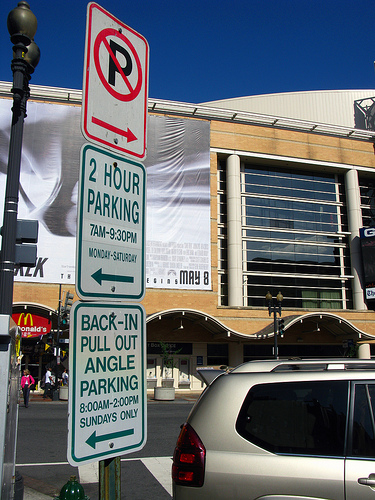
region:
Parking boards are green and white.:
[80, 161, 135, 427]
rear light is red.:
[167, 419, 218, 487]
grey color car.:
[179, 375, 372, 497]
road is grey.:
[32, 407, 56, 446]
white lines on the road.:
[140, 455, 173, 496]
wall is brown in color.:
[154, 293, 217, 311]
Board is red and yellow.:
[11, 306, 49, 351]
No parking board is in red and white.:
[87, 7, 159, 167]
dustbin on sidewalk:
[149, 384, 190, 409]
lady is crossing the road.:
[19, 371, 37, 398]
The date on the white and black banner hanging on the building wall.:
[176, 269, 212, 286]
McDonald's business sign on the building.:
[12, 309, 52, 337]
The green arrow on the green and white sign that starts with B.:
[81, 426, 141, 452]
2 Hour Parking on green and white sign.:
[87, 153, 145, 227]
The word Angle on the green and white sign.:
[83, 354, 140, 372]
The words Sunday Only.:
[79, 406, 141, 430]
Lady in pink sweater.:
[19, 364, 40, 407]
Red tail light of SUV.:
[162, 421, 208, 492]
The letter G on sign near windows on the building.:
[359, 225, 374, 237]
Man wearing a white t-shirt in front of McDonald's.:
[39, 361, 56, 402]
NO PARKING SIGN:
[79, 0, 157, 162]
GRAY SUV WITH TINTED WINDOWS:
[169, 351, 373, 498]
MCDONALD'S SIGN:
[5, 306, 55, 341]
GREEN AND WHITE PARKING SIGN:
[64, 300, 151, 467]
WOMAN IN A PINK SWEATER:
[17, 367, 38, 412]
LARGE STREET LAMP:
[2, 0, 46, 411]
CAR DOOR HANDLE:
[353, 470, 373, 493]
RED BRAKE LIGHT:
[166, 417, 210, 490]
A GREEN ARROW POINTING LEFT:
[85, 421, 139, 451]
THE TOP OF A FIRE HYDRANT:
[51, 472, 91, 496]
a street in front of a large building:
[27, 11, 342, 465]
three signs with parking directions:
[60, 0, 150, 473]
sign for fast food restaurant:
[0, 301, 57, 342]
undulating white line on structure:
[150, 300, 363, 372]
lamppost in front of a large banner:
[3, 0, 70, 325]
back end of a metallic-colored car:
[165, 336, 365, 486]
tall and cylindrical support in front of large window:
[206, 140, 262, 314]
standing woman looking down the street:
[16, 362, 38, 408]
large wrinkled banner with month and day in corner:
[153, 112, 214, 292]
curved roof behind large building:
[192, 77, 366, 144]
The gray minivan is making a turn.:
[164, 352, 374, 498]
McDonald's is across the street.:
[1, 290, 72, 391]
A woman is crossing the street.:
[16, 355, 43, 412]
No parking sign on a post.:
[70, 0, 154, 155]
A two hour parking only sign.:
[76, 150, 151, 305]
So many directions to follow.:
[63, 302, 149, 462]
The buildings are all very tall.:
[0, 71, 371, 397]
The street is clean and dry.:
[0, 386, 207, 496]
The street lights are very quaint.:
[0, 0, 53, 415]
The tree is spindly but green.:
[150, 333, 185, 405]